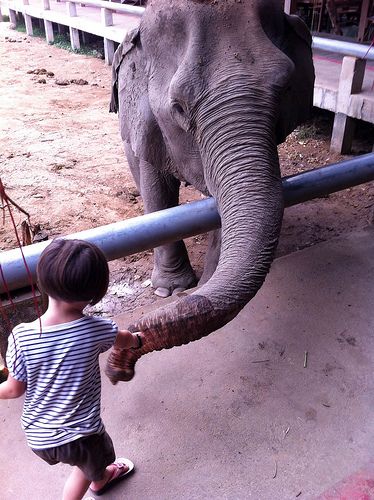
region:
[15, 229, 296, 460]
child touching elephant's trunk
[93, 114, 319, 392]
elephant's long grey trunk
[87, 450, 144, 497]
child wearing sandals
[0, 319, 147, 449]
child wearing stripped shirt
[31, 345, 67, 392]
stripes on child's shirt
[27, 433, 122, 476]
child wearing grey shorts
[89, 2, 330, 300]
baby grey elephant behind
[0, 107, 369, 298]
long grey tube surrounding elephant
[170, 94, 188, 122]
eye of grey elephant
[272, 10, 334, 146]
floppy ear of elephant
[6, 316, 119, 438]
black and white stripped shrt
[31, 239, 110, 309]
short hair on a girl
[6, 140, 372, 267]
mettal pole barrier from elephant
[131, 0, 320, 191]
a grey elphant face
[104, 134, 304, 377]
a big grey elephant trunk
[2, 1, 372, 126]
a wooden platform for people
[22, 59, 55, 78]
a pile of elephant dung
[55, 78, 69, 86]
a pile of elephant dung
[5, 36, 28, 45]
a pile of elephant dung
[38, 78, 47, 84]
a pile of elephant dung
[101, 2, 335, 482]
elephant in an enclosure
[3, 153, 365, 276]
bar around the enclosure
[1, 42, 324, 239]
dirt surface elephants walks on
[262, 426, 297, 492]
twigs on the ground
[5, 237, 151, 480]
child playing with elephant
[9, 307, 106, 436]
shirt on the child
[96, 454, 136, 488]
sandal on child's foot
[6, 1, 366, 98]
concrete area outside enclosure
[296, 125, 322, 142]
grass on the ground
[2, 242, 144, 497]
little girl with blue striped shirt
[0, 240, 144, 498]
little girl petting an elephant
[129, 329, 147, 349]
girl's hand on elephant's trunk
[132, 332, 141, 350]
bracelet on girl's wrist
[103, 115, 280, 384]
the elephant's trunk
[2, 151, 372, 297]
large, black, metal rail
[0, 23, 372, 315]
muddy ground in elephant pen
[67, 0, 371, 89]
railing behind the elephant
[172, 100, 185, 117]
the elephant's right eye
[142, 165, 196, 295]
the elephant's front right leg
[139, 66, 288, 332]
elephant has long trunk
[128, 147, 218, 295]
elephant has grey legs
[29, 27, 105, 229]
ground is brown and dry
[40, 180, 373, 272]
grey rail near trunk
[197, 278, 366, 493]
light brown concrete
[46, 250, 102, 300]
child has dark hair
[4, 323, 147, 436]
blue and white striped shirt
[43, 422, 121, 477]
child has grey shorts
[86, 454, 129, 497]
child has white sandals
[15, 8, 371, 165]
sidewalk runs behind elephant enclosure